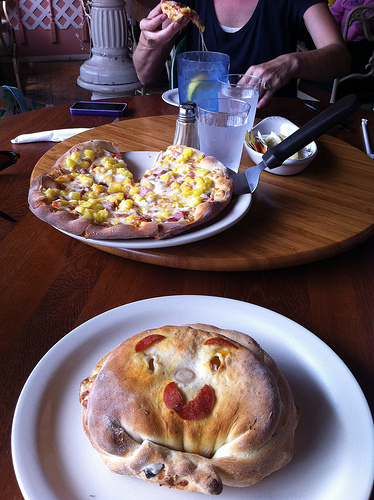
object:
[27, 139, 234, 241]
pizza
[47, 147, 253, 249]
plate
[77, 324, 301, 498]
foldover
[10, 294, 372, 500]
plate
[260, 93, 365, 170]
handle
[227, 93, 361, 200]
spatula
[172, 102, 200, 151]
pepper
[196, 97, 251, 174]
glass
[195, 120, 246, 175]
water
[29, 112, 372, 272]
platter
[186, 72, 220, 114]
lemon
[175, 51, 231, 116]
glass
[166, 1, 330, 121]
shirt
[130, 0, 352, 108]
person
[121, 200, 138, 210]
pineapple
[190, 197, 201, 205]
pinapple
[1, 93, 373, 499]
table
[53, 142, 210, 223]
toppings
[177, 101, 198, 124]
shaker top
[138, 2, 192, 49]
hand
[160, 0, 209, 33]
pizza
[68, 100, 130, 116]
cellphone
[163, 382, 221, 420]
pepperoni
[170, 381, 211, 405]
mouth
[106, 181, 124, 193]
pineapple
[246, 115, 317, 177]
bowl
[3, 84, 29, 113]
strap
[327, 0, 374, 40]
sweater